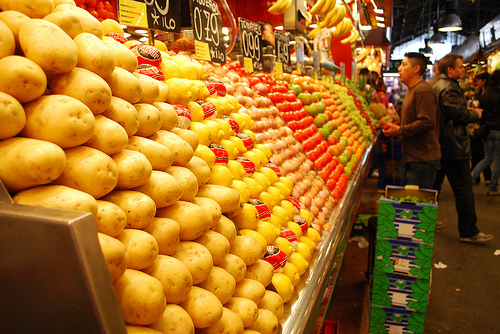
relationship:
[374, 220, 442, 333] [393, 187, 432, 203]
boxes has food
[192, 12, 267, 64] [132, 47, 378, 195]
price above food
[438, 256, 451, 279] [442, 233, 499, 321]
trash on ground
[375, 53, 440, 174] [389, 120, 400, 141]
man has hand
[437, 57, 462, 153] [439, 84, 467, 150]
man wearing jacket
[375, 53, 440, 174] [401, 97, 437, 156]
man wearing shirt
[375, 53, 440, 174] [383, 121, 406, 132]
man holding pepper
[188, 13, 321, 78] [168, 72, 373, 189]
signs above vegetables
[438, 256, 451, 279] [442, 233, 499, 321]
trash on sidewalk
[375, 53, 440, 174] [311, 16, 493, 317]
man in store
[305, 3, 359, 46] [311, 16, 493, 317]
bananas in store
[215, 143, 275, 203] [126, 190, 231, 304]
lemons besides potatoes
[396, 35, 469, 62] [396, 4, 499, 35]
lights on ceiling